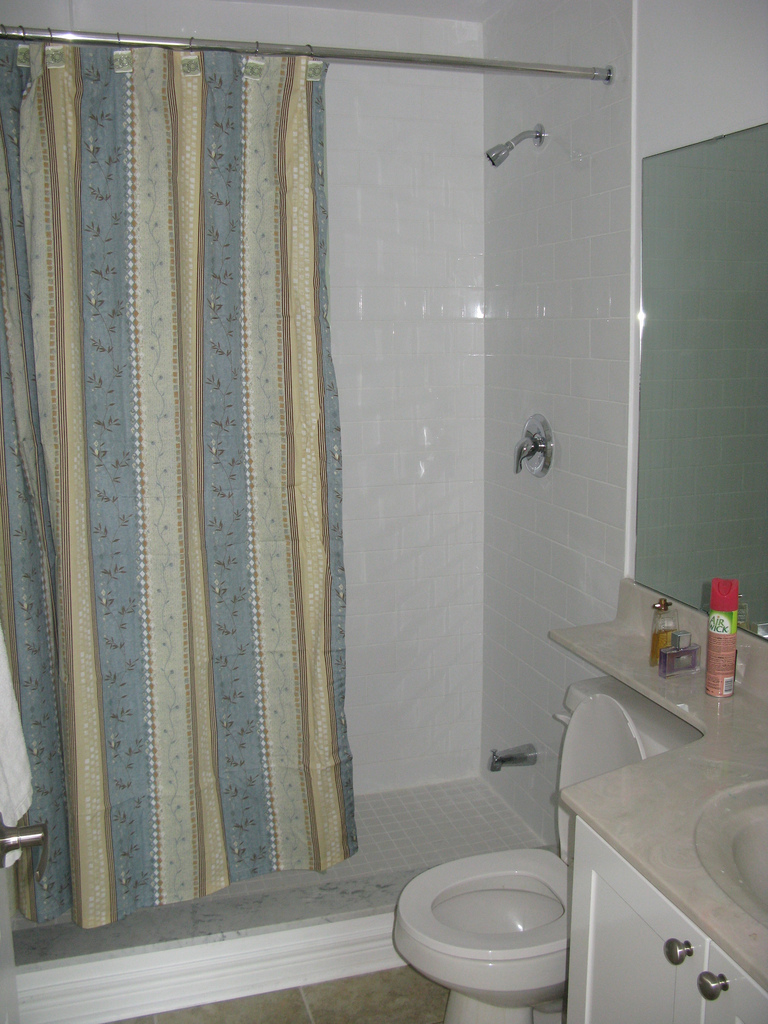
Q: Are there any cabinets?
A: Yes, there is a cabinet.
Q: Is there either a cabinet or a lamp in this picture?
A: Yes, there is a cabinet.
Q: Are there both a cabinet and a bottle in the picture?
A: Yes, there are both a cabinet and a bottle.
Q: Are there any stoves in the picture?
A: No, there are no stoves.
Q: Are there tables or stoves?
A: No, there are no stoves or tables.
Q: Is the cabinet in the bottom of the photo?
A: Yes, the cabinet is in the bottom of the image.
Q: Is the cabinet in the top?
A: No, the cabinet is in the bottom of the image.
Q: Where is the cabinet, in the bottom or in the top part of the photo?
A: The cabinet is in the bottom of the image.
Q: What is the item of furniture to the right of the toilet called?
A: The piece of furniture is a cabinet.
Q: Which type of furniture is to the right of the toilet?
A: The piece of furniture is a cabinet.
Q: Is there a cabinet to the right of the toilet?
A: Yes, there is a cabinet to the right of the toilet.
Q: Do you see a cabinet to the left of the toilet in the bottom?
A: No, the cabinet is to the right of the toilet.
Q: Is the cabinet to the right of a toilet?
A: Yes, the cabinet is to the right of a toilet.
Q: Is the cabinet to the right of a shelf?
A: No, the cabinet is to the right of a toilet.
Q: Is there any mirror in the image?
A: Yes, there is a mirror.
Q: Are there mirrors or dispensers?
A: Yes, there is a mirror.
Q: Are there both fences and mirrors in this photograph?
A: No, there is a mirror but no fences.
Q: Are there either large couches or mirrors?
A: Yes, there is a large mirror.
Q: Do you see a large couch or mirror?
A: Yes, there is a large mirror.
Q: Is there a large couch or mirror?
A: Yes, there is a large mirror.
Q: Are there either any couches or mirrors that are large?
A: Yes, the mirror is large.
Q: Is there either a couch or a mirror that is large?
A: Yes, the mirror is large.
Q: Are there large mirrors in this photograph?
A: Yes, there is a large mirror.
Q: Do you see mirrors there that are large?
A: Yes, there is a mirror that is large.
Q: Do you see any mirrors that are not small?
A: Yes, there is a large mirror.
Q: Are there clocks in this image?
A: No, there are no clocks.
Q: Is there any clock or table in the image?
A: No, there are no clocks or tables.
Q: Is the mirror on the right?
A: Yes, the mirror is on the right of the image.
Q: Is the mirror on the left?
A: No, the mirror is on the right of the image.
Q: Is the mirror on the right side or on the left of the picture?
A: The mirror is on the right of the image.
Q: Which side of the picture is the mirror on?
A: The mirror is on the right of the image.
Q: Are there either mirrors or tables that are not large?
A: No, there is a mirror but it is large.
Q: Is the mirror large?
A: Yes, the mirror is large.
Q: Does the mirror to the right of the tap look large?
A: Yes, the mirror is large.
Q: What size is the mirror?
A: The mirror is large.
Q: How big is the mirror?
A: The mirror is large.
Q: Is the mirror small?
A: No, the mirror is large.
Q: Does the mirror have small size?
A: No, the mirror is large.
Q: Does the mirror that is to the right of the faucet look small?
A: No, the mirror is large.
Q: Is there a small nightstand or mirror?
A: No, there is a mirror but it is large.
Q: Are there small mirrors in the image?
A: No, there is a mirror but it is large.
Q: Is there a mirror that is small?
A: No, there is a mirror but it is large.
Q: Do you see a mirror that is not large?
A: No, there is a mirror but it is large.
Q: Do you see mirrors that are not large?
A: No, there is a mirror but it is large.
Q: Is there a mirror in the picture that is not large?
A: No, there is a mirror but it is large.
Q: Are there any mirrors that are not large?
A: No, there is a mirror but it is large.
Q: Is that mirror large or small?
A: The mirror is large.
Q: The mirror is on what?
A: The mirror is on the wall.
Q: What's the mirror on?
A: The mirror is on the wall.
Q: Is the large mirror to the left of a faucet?
A: No, the mirror is to the right of a faucet.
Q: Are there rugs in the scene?
A: No, there are no rugs.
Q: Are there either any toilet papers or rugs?
A: No, there are no rugs or toilet papers.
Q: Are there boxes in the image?
A: No, there are no boxes.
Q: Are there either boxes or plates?
A: No, there are no boxes or plates.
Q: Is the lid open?
A: Yes, the lid is open.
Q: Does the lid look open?
A: Yes, the lid is open.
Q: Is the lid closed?
A: No, the lid is open.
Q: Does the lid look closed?
A: No, the lid is open.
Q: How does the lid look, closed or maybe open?
A: The lid is open.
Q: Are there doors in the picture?
A: Yes, there is a door.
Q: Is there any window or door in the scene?
A: Yes, there is a door.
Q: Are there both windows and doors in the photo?
A: No, there is a door but no windows.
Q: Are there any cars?
A: No, there are no cars.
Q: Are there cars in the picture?
A: No, there are no cars.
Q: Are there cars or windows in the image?
A: No, there are no cars or windows.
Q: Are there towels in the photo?
A: Yes, there is a towel.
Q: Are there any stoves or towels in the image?
A: Yes, there is a towel.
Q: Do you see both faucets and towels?
A: Yes, there are both a towel and a faucet.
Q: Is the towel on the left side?
A: Yes, the towel is on the left of the image.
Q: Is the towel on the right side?
A: No, the towel is on the left of the image.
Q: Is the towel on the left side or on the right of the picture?
A: The towel is on the left of the image.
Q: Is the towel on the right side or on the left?
A: The towel is on the left of the image.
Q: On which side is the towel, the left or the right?
A: The towel is on the left of the image.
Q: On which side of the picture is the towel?
A: The towel is on the left of the image.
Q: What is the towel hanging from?
A: The towel is hanging from the door.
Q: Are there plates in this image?
A: No, there are no plates.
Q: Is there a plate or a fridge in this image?
A: No, there are no plates or refrigerators.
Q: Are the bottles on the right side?
A: Yes, the bottles are on the right of the image.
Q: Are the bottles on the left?
A: No, the bottles are on the right of the image.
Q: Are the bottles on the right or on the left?
A: The bottles are on the right of the image.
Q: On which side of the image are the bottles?
A: The bottles are on the right of the image.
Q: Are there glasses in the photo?
A: No, there are no glasses.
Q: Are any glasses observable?
A: No, there are no glasses.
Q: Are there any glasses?
A: No, there are no glasses.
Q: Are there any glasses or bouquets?
A: No, there are no glasses or bouquets.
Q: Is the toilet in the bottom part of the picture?
A: Yes, the toilet is in the bottom of the image.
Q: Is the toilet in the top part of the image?
A: No, the toilet is in the bottom of the image.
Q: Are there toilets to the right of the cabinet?
A: No, the toilet is to the left of the cabinet.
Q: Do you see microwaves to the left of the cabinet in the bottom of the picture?
A: No, there is a toilet to the left of the cabinet.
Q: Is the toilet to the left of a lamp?
A: No, the toilet is to the left of a cabinet.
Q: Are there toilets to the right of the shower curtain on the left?
A: Yes, there is a toilet to the right of the shower curtain.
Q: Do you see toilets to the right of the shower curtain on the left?
A: Yes, there is a toilet to the right of the shower curtain.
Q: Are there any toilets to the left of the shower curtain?
A: No, the toilet is to the right of the shower curtain.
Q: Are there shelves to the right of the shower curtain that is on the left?
A: No, there is a toilet to the right of the shower curtain.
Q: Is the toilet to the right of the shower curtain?
A: Yes, the toilet is to the right of the shower curtain.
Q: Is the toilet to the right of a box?
A: No, the toilet is to the right of the shower curtain.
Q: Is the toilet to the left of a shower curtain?
A: No, the toilet is to the right of a shower curtain.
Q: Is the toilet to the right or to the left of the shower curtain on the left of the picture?
A: The toilet is to the right of the shower curtain.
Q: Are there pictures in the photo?
A: No, there are no pictures.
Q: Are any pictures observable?
A: No, there are no pictures.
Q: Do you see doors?
A: Yes, there are doors.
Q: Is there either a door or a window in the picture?
A: Yes, there are doors.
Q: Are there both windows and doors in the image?
A: No, there are doors but no windows.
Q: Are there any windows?
A: No, there are no windows.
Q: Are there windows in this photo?
A: No, there are no windows.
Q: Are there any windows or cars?
A: No, there are no windows or cars.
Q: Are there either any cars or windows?
A: No, there are no windows or cars.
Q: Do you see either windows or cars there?
A: No, there are no windows or cars.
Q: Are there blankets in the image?
A: No, there are no blankets.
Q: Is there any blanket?
A: No, there are no blankets.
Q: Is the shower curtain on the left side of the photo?
A: Yes, the shower curtain is on the left of the image.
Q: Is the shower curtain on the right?
A: No, the shower curtain is on the left of the image.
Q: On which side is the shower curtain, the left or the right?
A: The shower curtain is on the left of the image.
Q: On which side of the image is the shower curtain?
A: The shower curtain is on the left of the image.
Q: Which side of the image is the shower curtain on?
A: The shower curtain is on the left of the image.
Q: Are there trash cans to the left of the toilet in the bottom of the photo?
A: No, there is a shower curtain to the left of the toilet.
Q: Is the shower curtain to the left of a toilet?
A: Yes, the shower curtain is to the left of a toilet.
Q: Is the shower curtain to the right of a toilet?
A: No, the shower curtain is to the left of a toilet.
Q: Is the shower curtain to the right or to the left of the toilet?
A: The shower curtain is to the left of the toilet.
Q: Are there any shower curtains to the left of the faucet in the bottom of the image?
A: Yes, there is a shower curtain to the left of the tap.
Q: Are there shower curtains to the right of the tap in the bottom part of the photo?
A: No, the shower curtain is to the left of the tap.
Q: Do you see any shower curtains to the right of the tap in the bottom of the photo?
A: No, the shower curtain is to the left of the tap.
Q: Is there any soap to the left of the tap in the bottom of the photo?
A: No, there is a shower curtain to the left of the faucet.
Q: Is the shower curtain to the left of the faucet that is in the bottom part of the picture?
A: Yes, the shower curtain is to the left of the tap.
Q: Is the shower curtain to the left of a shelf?
A: No, the shower curtain is to the left of the tap.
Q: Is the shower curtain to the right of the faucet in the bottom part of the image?
A: No, the shower curtain is to the left of the tap.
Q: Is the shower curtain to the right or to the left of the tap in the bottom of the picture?
A: The shower curtain is to the left of the faucet.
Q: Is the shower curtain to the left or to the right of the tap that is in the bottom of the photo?
A: The shower curtain is to the left of the faucet.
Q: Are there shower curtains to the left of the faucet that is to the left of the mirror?
A: Yes, there is a shower curtain to the left of the faucet.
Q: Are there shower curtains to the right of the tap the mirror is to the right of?
A: No, the shower curtain is to the left of the faucet.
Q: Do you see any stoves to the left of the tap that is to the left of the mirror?
A: No, there is a shower curtain to the left of the faucet.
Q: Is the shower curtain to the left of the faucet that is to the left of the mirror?
A: Yes, the shower curtain is to the left of the tap.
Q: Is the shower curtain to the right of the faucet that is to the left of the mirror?
A: No, the shower curtain is to the left of the tap.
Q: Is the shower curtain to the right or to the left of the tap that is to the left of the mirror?
A: The shower curtain is to the left of the tap.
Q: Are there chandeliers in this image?
A: No, there are no chandeliers.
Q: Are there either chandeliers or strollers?
A: No, there are no chandeliers or strollers.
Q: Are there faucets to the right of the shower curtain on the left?
A: Yes, there is a faucet to the right of the shower curtain.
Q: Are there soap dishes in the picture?
A: No, there are no soap dishes.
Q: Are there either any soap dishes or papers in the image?
A: No, there are no soap dishes or papers.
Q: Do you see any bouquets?
A: No, there are no bouquets.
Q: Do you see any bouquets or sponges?
A: No, there are no bouquets or sponges.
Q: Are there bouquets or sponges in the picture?
A: No, there are no bouquets or sponges.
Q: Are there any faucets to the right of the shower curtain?
A: Yes, there is a faucet to the right of the shower curtain.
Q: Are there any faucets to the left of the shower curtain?
A: No, the faucet is to the right of the shower curtain.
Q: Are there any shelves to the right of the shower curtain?
A: No, there is a faucet to the right of the shower curtain.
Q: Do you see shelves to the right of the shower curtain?
A: No, there is a faucet to the right of the shower curtain.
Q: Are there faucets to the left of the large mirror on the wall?
A: Yes, there is a faucet to the left of the mirror.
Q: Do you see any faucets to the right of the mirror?
A: No, the faucet is to the left of the mirror.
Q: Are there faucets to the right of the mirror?
A: No, the faucet is to the left of the mirror.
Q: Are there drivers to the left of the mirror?
A: No, there is a faucet to the left of the mirror.